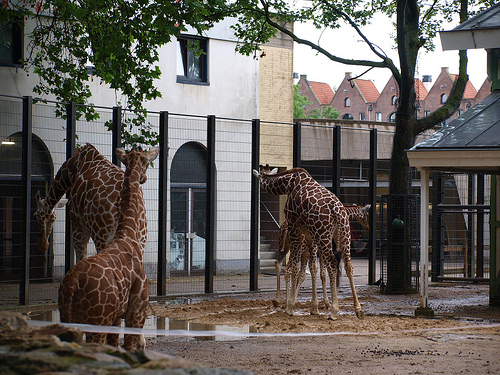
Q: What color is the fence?
A: Black.